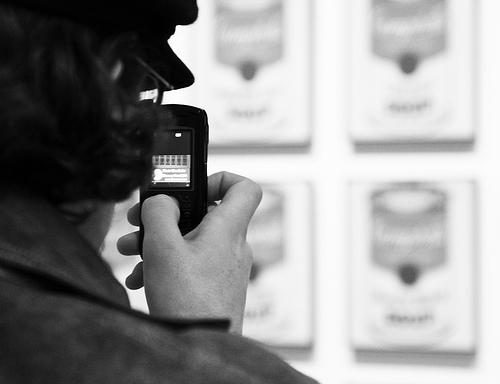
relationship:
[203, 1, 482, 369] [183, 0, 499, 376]
art on wall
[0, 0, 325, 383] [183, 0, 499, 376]
person in front of wall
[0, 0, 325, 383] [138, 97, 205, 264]
person holding phone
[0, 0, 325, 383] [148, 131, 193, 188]
person taking picture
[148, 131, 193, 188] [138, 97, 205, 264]
picture on phone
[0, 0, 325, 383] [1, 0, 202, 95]
person wearing hat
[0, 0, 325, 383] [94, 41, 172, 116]
person wearing glasses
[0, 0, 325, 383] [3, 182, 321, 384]
person wearing jacket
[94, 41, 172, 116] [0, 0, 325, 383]
glasses on person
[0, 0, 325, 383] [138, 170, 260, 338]
person has hand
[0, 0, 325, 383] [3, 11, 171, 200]
person has hair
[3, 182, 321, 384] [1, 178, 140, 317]
jacket has collar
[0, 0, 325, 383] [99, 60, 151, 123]
person has ear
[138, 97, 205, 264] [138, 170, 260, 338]
phone in hand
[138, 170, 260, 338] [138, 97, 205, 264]
hand holding phone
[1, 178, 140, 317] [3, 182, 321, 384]
collar on jacket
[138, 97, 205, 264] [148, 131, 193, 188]
phone taking picture